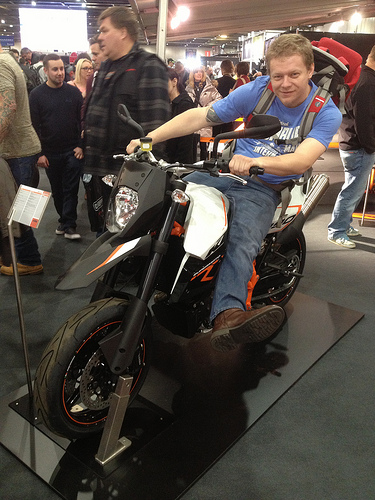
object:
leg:
[207, 197, 276, 312]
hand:
[228, 152, 257, 177]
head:
[265, 29, 315, 110]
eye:
[290, 66, 301, 81]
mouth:
[274, 85, 301, 97]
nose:
[280, 76, 291, 90]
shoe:
[210, 301, 286, 353]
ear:
[306, 63, 315, 81]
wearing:
[208, 76, 340, 309]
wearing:
[184, 68, 220, 157]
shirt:
[211, 73, 339, 190]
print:
[254, 123, 303, 159]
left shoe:
[209, 304, 286, 355]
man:
[29, 51, 82, 240]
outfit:
[30, 80, 84, 229]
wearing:
[73, 55, 97, 94]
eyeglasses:
[81, 63, 94, 71]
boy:
[124, 31, 342, 359]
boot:
[206, 301, 289, 357]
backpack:
[259, 36, 363, 141]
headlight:
[104, 184, 140, 232]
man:
[78, 5, 168, 234]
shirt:
[81, 56, 169, 232]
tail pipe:
[271, 172, 330, 255]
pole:
[4, 221, 35, 418]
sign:
[7, 183, 51, 230]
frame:
[115, 241, 166, 356]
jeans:
[209, 202, 276, 309]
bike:
[27, 99, 308, 448]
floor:
[232, 447, 288, 480]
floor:
[256, 422, 302, 462]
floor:
[260, 464, 295, 489]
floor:
[290, 460, 326, 489]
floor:
[293, 391, 349, 452]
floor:
[324, 454, 369, 491]